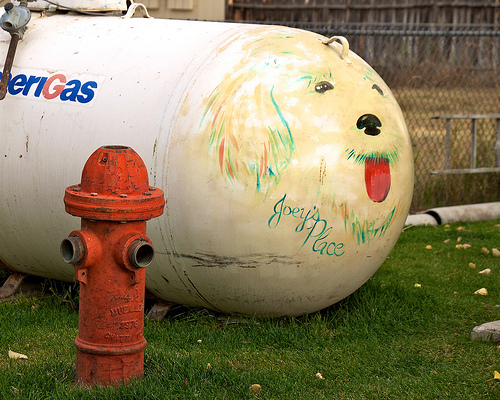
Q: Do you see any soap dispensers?
A: No, there are no soap dispensers.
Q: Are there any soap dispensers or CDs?
A: No, there are no soap dispensers or cds.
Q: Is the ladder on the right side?
A: Yes, the ladder is on the right of the image.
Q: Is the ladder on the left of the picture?
A: No, the ladder is on the right of the image.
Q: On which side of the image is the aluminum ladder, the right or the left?
A: The ladder is on the right of the image.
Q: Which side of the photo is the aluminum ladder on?
A: The ladder is on the right of the image.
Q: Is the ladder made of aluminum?
A: Yes, the ladder is made of aluminum.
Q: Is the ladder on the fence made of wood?
A: No, the ladder is made of aluminum.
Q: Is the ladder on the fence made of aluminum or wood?
A: The ladder is made of aluminum.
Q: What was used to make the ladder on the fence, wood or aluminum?
A: The ladder is made of aluminum.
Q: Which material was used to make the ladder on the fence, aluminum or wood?
A: The ladder is made of aluminum.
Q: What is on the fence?
A: The ladder is on the fence.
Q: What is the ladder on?
A: The ladder is on the fence.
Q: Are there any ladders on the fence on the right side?
A: Yes, there is a ladder on the fence.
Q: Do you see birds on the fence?
A: No, there is a ladder on the fence.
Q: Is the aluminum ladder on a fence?
A: Yes, the ladder is on a fence.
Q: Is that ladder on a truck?
A: No, the ladder is on a fence.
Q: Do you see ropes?
A: No, there are no ropes.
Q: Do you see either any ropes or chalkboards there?
A: No, there are no ropes or chalkboards.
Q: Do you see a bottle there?
A: No, there are no bottles.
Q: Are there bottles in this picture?
A: No, there are no bottles.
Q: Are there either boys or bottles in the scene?
A: No, there are no bottles or boys.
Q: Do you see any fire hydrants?
A: Yes, there is a fire hydrant.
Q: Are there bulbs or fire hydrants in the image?
A: Yes, there is a fire hydrant.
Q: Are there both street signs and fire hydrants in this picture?
A: No, there is a fire hydrant but no street signs.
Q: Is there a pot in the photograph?
A: No, there are no pots.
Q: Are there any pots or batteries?
A: No, there are no pots or batteries.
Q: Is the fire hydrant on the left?
A: Yes, the fire hydrant is on the left of the image.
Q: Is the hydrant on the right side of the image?
A: No, the hydrant is on the left of the image.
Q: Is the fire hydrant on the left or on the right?
A: The fire hydrant is on the left of the image.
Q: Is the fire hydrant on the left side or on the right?
A: The fire hydrant is on the left of the image.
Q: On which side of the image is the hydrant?
A: The hydrant is on the left of the image.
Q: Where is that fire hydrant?
A: The fire hydrant is on the grass.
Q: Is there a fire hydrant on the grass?
A: Yes, there is a fire hydrant on the grass.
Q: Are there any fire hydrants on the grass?
A: Yes, there is a fire hydrant on the grass.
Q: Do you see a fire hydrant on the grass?
A: Yes, there is a fire hydrant on the grass.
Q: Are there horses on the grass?
A: No, there is a fire hydrant on the grass.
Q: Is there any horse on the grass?
A: No, there is a fire hydrant on the grass.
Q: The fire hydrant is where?
A: The fire hydrant is in the grass.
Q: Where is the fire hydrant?
A: The fire hydrant is in the grass.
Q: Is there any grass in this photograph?
A: Yes, there is grass.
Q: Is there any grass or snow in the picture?
A: Yes, there is grass.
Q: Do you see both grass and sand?
A: No, there is grass but no sand.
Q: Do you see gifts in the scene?
A: No, there are no gifts.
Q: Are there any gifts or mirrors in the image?
A: No, there are no gifts or mirrors.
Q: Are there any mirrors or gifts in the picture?
A: No, there are no gifts or mirrors.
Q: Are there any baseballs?
A: No, there are no baseballs.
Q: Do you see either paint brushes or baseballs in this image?
A: No, there are no baseballs or paint brushes.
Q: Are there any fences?
A: Yes, there is a fence.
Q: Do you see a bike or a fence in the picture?
A: Yes, there is a fence.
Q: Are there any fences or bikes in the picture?
A: Yes, there is a fence.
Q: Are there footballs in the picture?
A: No, there are no footballs.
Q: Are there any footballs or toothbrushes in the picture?
A: No, there are no footballs or toothbrushes.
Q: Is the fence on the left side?
A: No, the fence is on the right of the image.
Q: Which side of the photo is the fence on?
A: The fence is on the right of the image.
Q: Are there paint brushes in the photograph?
A: No, there are no paint brushes.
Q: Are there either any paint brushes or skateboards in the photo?
A: No, there are no paint brushes or skateboards.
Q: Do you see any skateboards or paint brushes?
A: No, there are no paint brushes or skateboards.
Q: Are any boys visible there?
A: No, there are no boys.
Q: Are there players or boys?
A: No, there are no boys or players.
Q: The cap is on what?
A: The cap is on the hydrant.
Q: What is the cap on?
A: The cap is on the hydrant.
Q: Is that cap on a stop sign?
A: No, the cap is on a fire hydrant.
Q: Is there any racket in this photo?
A: No, there are no rackets.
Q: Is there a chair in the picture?
A: No, there are no chairs.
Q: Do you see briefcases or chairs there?
A: No, there are no chairs or briefcases.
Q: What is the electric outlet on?
A: The electric outlet is on the hydrant.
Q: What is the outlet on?
A: The electric outlet is on the hydrant.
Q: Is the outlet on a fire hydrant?
A: Yes, the outlet is on a fire hydrant.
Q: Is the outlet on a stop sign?
A: No, the outlet is on a fire hydrant.